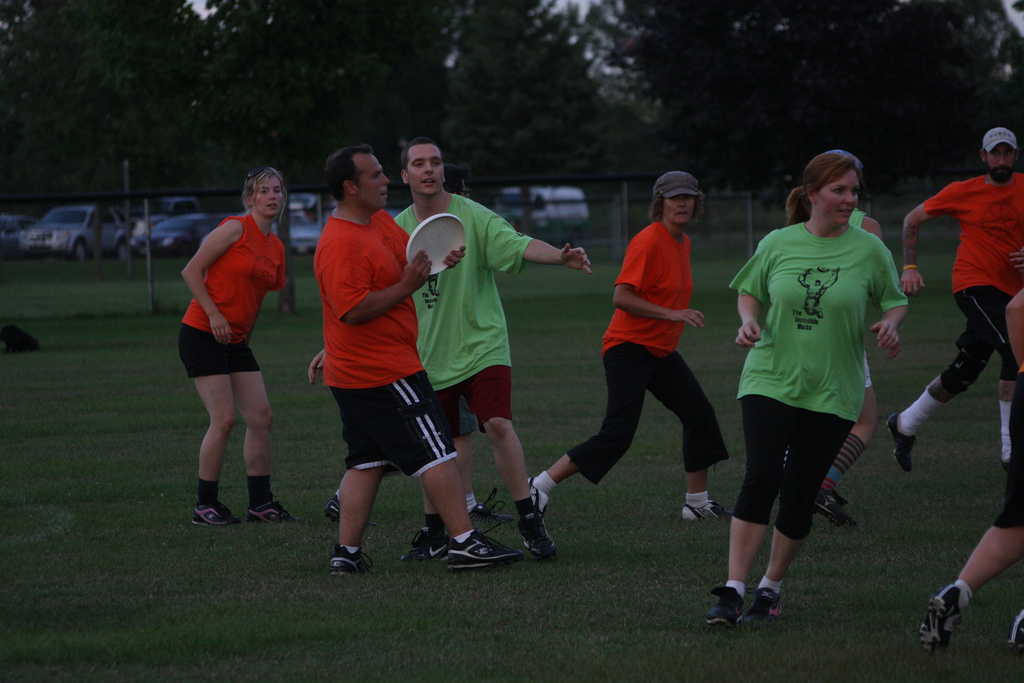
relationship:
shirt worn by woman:
[178, 200, 293, 350] [130, 72, 321, 582]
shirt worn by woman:
[615, 220, 702, 367] [582, 147, 736, 532]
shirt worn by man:
[318, 207, 408, 389] [282, 135, 520, 585]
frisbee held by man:
[402, 204, 469, 310] [254, 117, 523, 582]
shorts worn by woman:
[168, 318, 263, 382] [96, 135, 325, 561]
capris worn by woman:
[740, 391, 839, 544] [684, 113, 935, 678]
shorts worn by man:
[333, 366, 454, 469] [269, 124, 507, 643]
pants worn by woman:
[592, 349, 720, 485] [506, 124, 822, 598]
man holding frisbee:
[406, 207, 471, 294] [386, 210, 490, 310]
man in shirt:
[311, 138, 588, 554] [398, 189, 612, 416]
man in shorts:
[311, 138, 588, 554] [435, 333, 529, 467]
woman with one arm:
[141, 113, 308, 608] [126, 178, 295, 379]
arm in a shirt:
[126, 178, 295, 379] [139, 208, 300, 362]